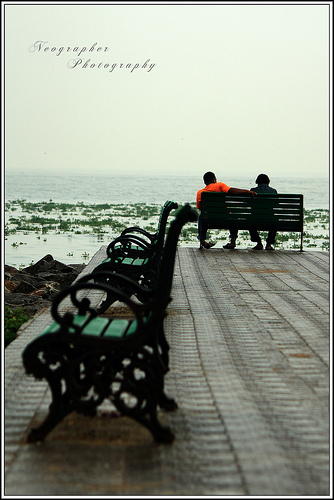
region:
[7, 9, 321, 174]
hazy white skies above the ocean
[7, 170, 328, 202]
calm ocean in the distance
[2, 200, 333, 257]
beach dotted with grass patches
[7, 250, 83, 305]
large rocks next to boardwalk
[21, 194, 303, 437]
benches on the boardwalk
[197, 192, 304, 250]
bench people are sitting on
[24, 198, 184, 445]
row of three green and black benches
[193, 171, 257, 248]
man with his arm propped on the bench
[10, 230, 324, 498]
boardwalk on the sand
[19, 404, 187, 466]
shadow of the bench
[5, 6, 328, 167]
light in daytime sky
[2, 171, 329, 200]
surface of rough water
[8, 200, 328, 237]
patches of green grass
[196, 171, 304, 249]
two people on bench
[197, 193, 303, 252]
back of park bench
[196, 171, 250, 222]
man in orange shirt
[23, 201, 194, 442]
row of empty benches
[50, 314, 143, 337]
green seat of bench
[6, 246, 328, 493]
ridged surface under benches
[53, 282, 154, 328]
curved arm on bench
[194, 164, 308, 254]
Two people on park bench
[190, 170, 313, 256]
Two people on bench facing ocean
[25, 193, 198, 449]
Three empty park benches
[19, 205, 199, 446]
Metal and wood park bench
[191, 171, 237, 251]
Man in orange sitting down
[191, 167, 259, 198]
Man with right arm draped over bench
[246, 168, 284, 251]
Person with grey top sitting on bench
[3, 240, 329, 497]
Grey cement area holding benches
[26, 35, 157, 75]
Photo copyrighted to Neography Photography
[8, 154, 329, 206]
Ocean on foggy day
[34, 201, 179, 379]
these are the benches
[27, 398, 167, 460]
these are the legs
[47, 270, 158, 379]
the bench is empty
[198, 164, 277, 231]
these are two men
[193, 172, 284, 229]
the men are sitted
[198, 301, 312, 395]
this is the floor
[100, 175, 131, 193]
this is the sea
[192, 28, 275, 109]
this is the sky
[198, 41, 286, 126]
the sky is white in color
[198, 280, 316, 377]
the floor is clean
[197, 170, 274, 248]
two people sitting on a bench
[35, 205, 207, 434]
three unoccupied benches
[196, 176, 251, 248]
man wearing orange shirt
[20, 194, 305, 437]
four benches on the boardwalk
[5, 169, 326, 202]
ocean waters in the distance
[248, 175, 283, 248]
person wearing dark green shirt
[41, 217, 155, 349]
black armrests on the benches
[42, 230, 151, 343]
green seats on the benches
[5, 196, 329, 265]
sandy expanse in front of the boardwalk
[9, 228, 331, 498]
boardwalk the benches are on